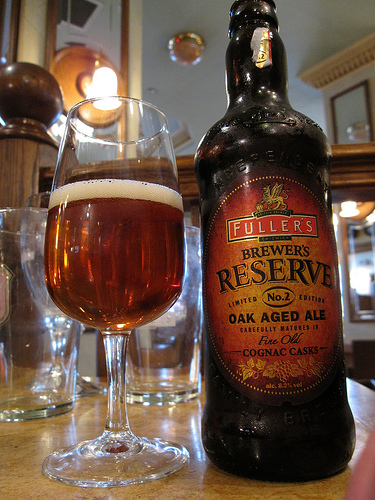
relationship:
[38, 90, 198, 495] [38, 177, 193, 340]
glass with beer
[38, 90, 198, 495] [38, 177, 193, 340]
glass filled with beer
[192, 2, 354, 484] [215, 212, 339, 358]
bottle of fuller's ale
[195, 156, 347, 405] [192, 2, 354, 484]
label on bottle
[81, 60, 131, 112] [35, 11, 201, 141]
glowing fixture on wall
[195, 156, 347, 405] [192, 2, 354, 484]
label on side bottle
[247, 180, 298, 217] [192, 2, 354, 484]
design on side of glass bottle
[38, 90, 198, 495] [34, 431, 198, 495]
glass has a base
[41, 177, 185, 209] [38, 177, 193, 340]
foam on top beer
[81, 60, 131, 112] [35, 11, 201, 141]
light on wall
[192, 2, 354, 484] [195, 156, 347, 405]
bottle has label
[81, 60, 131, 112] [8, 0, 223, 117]
light hanging on ceiling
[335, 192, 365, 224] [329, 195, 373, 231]
light hanging on plaque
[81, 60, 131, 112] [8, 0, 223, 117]
light in ceiling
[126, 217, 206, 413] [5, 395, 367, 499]
glass on table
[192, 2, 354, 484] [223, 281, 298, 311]
bottle says limited no 2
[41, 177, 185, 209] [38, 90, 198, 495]
foam in glass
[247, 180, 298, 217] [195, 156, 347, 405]
flying lion on top label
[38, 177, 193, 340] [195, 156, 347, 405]
beer brewed in family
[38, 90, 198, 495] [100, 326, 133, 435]
glass has a stem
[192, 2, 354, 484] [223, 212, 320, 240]
beer brand fuller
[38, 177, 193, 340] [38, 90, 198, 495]
beer in a glass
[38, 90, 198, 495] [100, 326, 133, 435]
glass has stem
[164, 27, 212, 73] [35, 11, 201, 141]
fixture on wall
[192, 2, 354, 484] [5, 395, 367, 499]
bottle on table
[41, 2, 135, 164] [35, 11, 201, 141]
mirror on wall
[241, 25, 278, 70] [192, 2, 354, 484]
sticker on bottle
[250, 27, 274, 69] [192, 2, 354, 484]
sticker on bottle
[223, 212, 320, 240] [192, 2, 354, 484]
name on bottle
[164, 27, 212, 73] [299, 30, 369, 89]
design on moulding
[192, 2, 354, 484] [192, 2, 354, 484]
bottle of beer